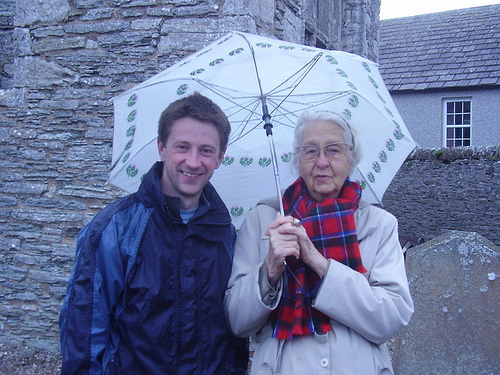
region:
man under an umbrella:
[56, 91, 242, 373]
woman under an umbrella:
[247, 105, 416, 367]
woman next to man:
[250, 101, 424, 372]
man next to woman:
[72, 95, 242, 365]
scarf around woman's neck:
[287, 166, 370, 326]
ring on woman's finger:
[289, 210, 313, 242]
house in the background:
[391, 22, 496, 164]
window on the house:
[430, 89, 491, 150]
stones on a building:
[16, 109, 78, 205]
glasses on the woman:
[291, 126, 356, 170]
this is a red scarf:
[260, 163, 375, 347]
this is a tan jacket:
[226, 186, 428, 372]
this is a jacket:
[48, 135, 269, 373]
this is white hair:
[280, 99, 367, 171]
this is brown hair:
[148, 74, 245, 161]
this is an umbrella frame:
[212, 73, 321, 148]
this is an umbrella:
[97, 10, 427, 296]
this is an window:
[433, 91, 488, 159]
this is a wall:
[376, 129, 499, 244]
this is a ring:
[283, 210, 309, 243]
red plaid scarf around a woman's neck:
[276, 176, 369, 341]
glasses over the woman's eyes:
[289, 141, 350, 161]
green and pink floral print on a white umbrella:
[240, 153, 253, 168]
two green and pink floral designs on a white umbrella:
[235, 155, 275, 168]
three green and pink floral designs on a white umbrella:
[221, 154, 272, 170]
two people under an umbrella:
[53, 29, 419, 369]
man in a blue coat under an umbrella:
[68, 85, 235, 374]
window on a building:
[435, 94, 472, 146]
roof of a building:
[378, 6, 498, 89]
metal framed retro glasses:
[291, 140, 353, 165]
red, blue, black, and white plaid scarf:
[267, 177, 369, 344]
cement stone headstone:
[390, 228, 499, 373]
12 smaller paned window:
[440, 97, 475, 152]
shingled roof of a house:
[376, 3, 498, 95]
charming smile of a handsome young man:
[175, 168, 203, 178]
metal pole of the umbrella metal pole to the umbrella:
[265, 132, 295, 268]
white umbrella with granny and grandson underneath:
[105, 27, 417, 231]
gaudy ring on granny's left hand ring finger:
[292, 217, 302, 227]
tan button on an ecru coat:
[319, 357, 329, 368]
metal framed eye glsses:
[294, 142, 353, 164]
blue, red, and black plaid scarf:
[267, 177, 369, 342]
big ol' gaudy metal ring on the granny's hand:
[291, 215, 302, 229]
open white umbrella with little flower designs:
[107, 27, 419, 230]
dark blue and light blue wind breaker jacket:
[57, 161, 246, 373]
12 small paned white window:
[441, 97, 475, 150]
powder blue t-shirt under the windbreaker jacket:
[178, 205, 198, 225]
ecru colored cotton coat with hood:
[223, 194, 415, 373]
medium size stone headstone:
[392, 229, 498, 374]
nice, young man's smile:
[175, 167, 205, 181]